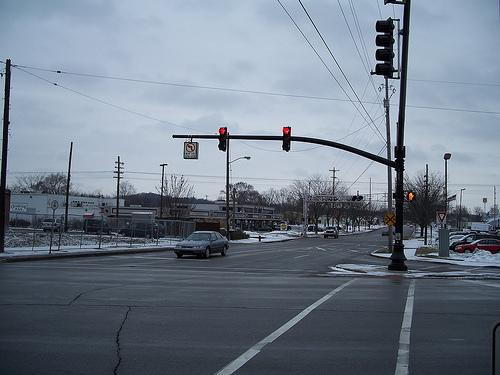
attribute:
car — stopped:
[171, 229, 231, 261]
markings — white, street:
[208, 274, 418, 373]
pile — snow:
[469, 242, 484, 263]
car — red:
[452, 232, 484, 253]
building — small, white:
[5, 189, 125, 228]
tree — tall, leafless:
[217, 178, 262, 218]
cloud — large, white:
[47, 110, 254, 190]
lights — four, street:
[372, 16, 399, 82]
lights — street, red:
[217, 125, 293, 152]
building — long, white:
[7, 190, 127, 230]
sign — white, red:
[181, 138, 200, 161]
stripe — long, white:
[391, 274, 417, 373]